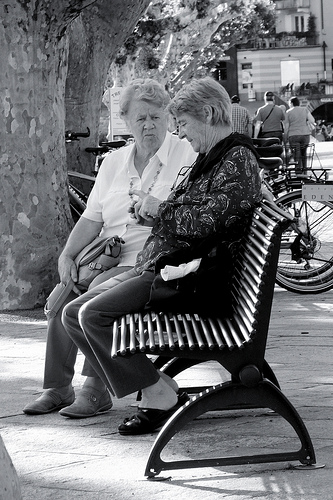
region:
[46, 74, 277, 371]
two women sitting on a bench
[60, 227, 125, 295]
purse in the woman's lap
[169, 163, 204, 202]
glasses around woman's neck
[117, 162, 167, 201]
necklace around woman's neck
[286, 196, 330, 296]
wheel on a bike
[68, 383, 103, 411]
shoe on woman's foot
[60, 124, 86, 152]
handle on a bike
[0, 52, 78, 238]
tree trunk near bench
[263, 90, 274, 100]
hat on man's head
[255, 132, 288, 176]
seats on bikes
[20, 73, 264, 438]
two elderly women sitting on a park bench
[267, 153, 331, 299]
bicycles parked at a bike rack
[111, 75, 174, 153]
grey-haired woman looking perplexed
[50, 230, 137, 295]
woman's purse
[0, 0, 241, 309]
trees behind the women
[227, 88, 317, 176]
three people walking down the street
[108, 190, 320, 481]
park bench on the sidewalk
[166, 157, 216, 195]
glasses hanging from a woman's neck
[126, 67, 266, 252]
woman gesturing with her hands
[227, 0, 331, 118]
building in the background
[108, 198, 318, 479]
bench with two ladies on it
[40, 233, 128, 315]
handbag in woman's hand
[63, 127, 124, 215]
part of a bicycle between to trees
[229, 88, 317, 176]
three people walking away in the distance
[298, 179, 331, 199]
white sign on the back of a bike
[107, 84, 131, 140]
half of a white sign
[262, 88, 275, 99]
man wearing a black hat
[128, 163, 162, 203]
long beaded necklace on the white shirt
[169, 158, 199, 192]
glasses hanging around the lady's neck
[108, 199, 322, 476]
a metal park bench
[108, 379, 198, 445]
a black pair of clogs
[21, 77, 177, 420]
a lady holds her handbag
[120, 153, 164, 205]
a beaded necklace over a white shirt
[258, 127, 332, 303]
back ends of parked bicycles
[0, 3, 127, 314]
trunk appear to be of sycamores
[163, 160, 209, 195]
eyeglasses hang from a neck lace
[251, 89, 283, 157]
a man carries a shoulder bag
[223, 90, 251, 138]
a man wearing a plaid shirt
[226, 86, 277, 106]
two men wearing baseball caps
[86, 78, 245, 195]
two elderly women with light hair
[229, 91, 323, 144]
backs of three people walking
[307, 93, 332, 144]
dark entrance to a tunnel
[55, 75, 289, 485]
two woman sitting on a bench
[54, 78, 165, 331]
woman holding purse in lab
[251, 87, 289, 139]
man with strap across back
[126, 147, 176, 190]
necklace on a white shirt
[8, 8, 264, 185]
two women under a tree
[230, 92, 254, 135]
back of man wearing checked shirt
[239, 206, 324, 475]
back of a park bench